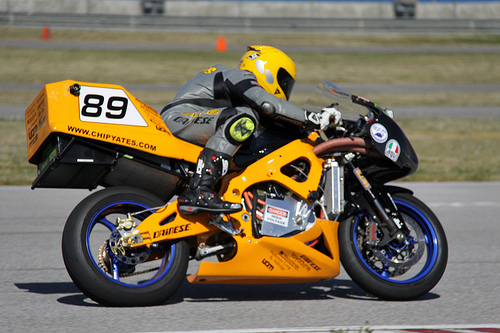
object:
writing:
[82, 92, 129, 120]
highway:
[0, 175, 499, 330]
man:
[159, 44, 344, 218]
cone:
[213, 33, 230, 52]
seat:
[162, 118, 329, 172]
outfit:
[157, 61, 320, 165]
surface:
[1, 183, 62, 330]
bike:
[24, 75, 449, 311]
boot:
[176, 180, 246, 217]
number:
[79, 92, 131, 120]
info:
[65, 123, 159, 152]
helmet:
[239, 42, 299, 101]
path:
[4, 30, 498, 53]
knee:
[208, 106, 261, 139]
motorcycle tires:
[56, 183, 190, 304]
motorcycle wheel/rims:
[338, 186, 452, 300]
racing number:
[80, 90, 131, 123]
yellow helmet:
[240, 43, 299, 99]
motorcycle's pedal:
[204, 208, 244, 235]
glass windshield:
[298, 82, 375, 121]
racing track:
[0, 183, 500, 331]